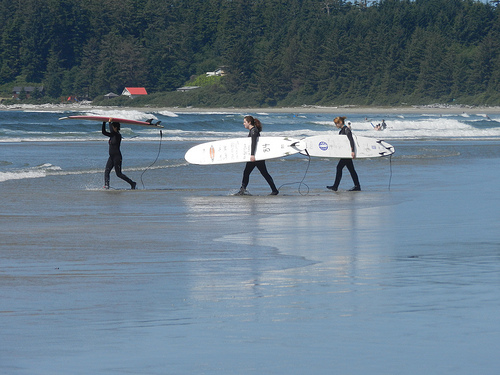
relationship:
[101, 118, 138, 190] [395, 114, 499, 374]
surfer on beach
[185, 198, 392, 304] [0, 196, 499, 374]
reflection on sand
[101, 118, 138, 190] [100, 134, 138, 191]
surfers have black wetsuits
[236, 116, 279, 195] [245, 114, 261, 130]
surfer in a pony tail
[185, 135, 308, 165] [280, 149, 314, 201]
surfboards have tether leash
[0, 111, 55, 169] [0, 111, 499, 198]
blue waters for surfing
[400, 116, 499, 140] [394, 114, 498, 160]
waves along shoreline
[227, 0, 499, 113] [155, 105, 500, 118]
trees along shoreline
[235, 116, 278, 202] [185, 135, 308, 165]
surfer carrying a surfboard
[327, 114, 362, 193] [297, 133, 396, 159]
surfer carrying surfboard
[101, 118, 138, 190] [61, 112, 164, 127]
surfer carrying a surfboard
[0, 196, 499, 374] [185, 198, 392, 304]
wet sand has a reflection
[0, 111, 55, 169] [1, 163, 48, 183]
water has ripples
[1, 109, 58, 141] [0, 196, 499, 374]
an ocean and beach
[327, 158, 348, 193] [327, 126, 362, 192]
womans leg covered in a wetsuit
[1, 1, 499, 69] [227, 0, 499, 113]
forest of evergreens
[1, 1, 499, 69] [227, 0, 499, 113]
forest of evergreen pine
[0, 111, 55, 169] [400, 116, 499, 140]
ocean has waves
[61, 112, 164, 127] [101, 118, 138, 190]
surfboard over her head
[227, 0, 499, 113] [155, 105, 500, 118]
evergreens on shoreline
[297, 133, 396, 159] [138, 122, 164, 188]
surfboard has a tether line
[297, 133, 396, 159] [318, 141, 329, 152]
surfboard has a logo brand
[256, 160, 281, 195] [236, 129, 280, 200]
legs are covered by a wetsuit